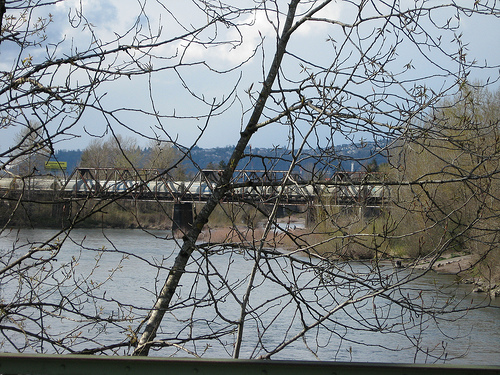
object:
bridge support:
[171, 202, 206, 233]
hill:
[1, 138, 398, 177]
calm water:
[18, 227, 150, 312]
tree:
[0, 0, 264, 368]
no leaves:
[4, 1, 184, 181]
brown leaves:
[391, 113, 499, 230]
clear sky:
[0, 0, 500, 150]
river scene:
[0, 0, 500, 370]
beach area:
[391, 251, 498, 293]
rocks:
[461, 278, 500, 298]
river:
[0, 227, 500, 367]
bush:
[175, 81, 500, 257]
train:
[0, 176, 388, 200]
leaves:
[296, 30, 472, 152]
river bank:
[193, 225, 500, 299]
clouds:
[63, 10, 286, 65]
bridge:
[1, 178, 389, 236]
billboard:
[45, 161, 68, 170]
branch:
[0, 0, 500, 368]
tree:
[131, 0, 496, 359]